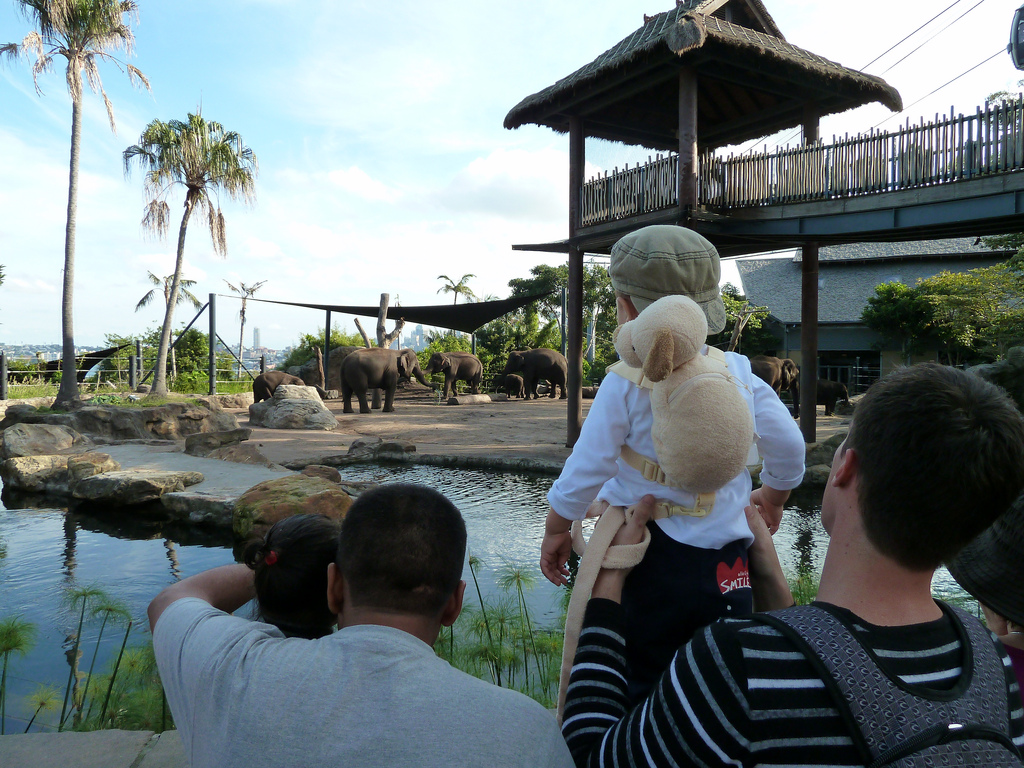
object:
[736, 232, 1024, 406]
building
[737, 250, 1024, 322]
wall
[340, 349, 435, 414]
animal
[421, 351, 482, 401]
animal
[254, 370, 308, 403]
animal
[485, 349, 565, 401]
animal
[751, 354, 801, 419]
animal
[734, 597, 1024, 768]
backpack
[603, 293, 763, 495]
backpack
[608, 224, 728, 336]
hat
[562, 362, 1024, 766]
man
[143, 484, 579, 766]
man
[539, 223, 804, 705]
child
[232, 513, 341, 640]
child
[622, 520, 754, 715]
pants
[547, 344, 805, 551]
shirt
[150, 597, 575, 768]
shirt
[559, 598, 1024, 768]
shirt